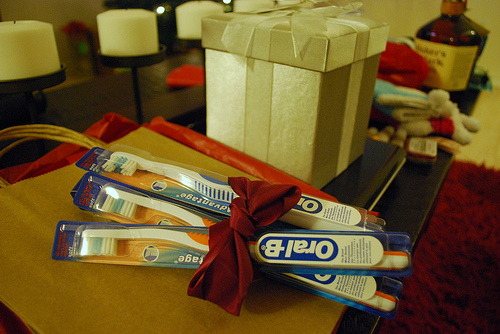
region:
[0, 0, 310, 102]
five white candles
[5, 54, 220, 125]
candles are on black candle holder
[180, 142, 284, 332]
toothbrushes are tied together with a bow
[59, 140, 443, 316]
toothbrushes on top of gift bag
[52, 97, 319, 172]
red tissue paper under gift bag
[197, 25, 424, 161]
gift box is wrapped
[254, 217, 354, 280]
brand of toothbrushes is Oral-B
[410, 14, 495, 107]
liquor bottle on the table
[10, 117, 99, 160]
handles of gift bags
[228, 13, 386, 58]
gift box has a bow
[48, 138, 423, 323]
three toothbrushes wrapped in a bow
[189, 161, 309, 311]
red bow around toothbrushes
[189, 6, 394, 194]
box that a gift would come in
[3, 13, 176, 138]
candles on candlestands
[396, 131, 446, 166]
box of Altoids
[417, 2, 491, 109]
bottle of something on the table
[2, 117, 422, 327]
three toothbrushes on top of a gift bag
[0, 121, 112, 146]
handles of a gift bag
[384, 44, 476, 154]
clothing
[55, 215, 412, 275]
toothbrush new in the package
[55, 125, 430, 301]
toothbrushes wrapped in bow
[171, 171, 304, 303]
the bow is red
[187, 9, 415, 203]
gold colored gift box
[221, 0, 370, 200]
bow tie is white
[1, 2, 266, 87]
white candles behind gift box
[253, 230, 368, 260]
blue background on packaging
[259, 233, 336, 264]
letters say oral b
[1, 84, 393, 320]
toothbrushes laying on bag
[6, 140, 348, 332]
bag made of paper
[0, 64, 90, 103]
candle holders are black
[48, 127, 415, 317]
toothbrushes held together by ribbon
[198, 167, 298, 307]
red ribbon tied into bow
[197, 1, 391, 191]
metallic gold gift box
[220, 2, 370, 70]
sheer gold ribbon on gift box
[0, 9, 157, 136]
candle holder with white candles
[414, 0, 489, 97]
bottle of Maker's Mark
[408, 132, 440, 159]
red and white altoids tin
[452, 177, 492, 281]
red shaggy area rug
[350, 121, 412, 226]
laptop underneath gifts being wrapped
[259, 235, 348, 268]
blue and white logo on toothbrushes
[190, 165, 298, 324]
red ribbon tied into a bow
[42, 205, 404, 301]
new packaged toothbrush on table top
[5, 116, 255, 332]
yellow paper gift bag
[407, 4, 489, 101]
bottle of whiskey on table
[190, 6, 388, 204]
square silver gift box with bow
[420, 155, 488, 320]
red fuzzy shag carpeting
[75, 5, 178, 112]
white candle on tall candle holder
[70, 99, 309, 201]
red accent gift tissue paper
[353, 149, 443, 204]
brown wooden table top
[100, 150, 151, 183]
blue and white toothbrush bristles